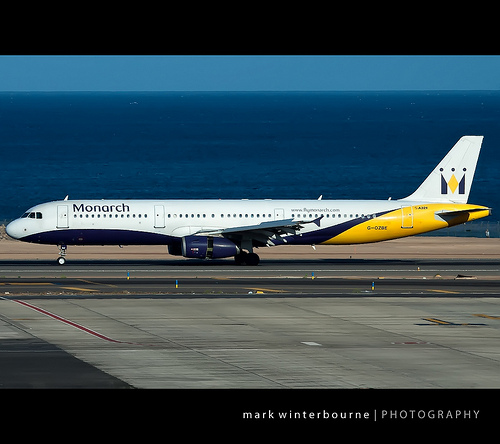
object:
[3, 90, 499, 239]
water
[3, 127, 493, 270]
jet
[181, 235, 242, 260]
left engine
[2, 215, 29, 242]
nose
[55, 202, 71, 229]
door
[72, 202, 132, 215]
monarch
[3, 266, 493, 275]
line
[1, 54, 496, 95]
sky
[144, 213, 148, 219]
window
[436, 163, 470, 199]
symbol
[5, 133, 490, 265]
plane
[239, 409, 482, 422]
text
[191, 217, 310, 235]
left wing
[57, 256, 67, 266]
front wheel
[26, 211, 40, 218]
window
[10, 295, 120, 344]
stripe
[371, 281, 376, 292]
post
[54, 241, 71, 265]
front landing gear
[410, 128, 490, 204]
tail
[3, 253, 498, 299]
runway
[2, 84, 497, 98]
horizon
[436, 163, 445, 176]
dot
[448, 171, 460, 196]
diamond